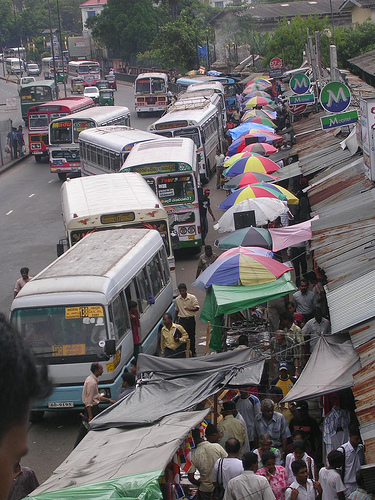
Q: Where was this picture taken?
A: Street.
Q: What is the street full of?
A: Busses.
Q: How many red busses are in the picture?
A: One.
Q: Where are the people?
A: Market.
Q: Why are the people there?
A: Shopping.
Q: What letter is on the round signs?
A: M.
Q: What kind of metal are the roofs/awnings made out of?
A: Corrugated.